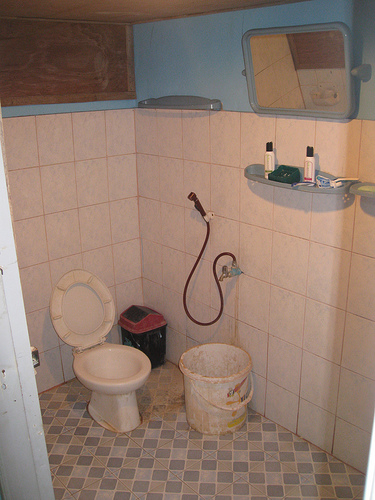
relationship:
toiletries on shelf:
[262, 140, 360, 187] [243, 159, 344, 198]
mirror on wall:
[242, 21, 354, 117] [132, 1, 373, 117]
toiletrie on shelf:
[304, 145, 314, 181] [245, 162, 348, 193]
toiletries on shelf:
[263, 140, 275, 179] [245, 162, 348, 193]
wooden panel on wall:
[0, 17, 130, 94] [127, 23, 135, 96]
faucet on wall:
[210, 257, 242, 282] [264, 229, 321, 335]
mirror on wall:
[248, 29, 347, 114] [130, 0, 372, 475]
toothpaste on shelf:
[321, 165, 372, 204] [238, 161, 373, 197]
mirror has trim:
[248, 29, 347, 114] [339, 26, 361, 120]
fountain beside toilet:
[173, 179, 253, 337] [41, 263, 153, 434]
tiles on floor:
[117, 454, 233, 495] [46, 378, 303, 498]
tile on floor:
[175, 454, 240, 499] [37, 362, 363, 499]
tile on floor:
[44, 429, 86, 469] [37, 362, 363, 499]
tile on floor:
[241, 419, 297, 458] [37, 362, 363, 499]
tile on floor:
[87, 431, 145, 473] [37, 362, 363, 499]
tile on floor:
[125, 415, 180, 454] [37, 362, 363, 499]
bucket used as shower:
[167, 341, 345, 383] [173, 171, 250, 329]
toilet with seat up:
[41, 263, 153, 434] [47, 264, 116, 347]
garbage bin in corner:
[119, 304, 166, 368] [118, 117, 166, 295]